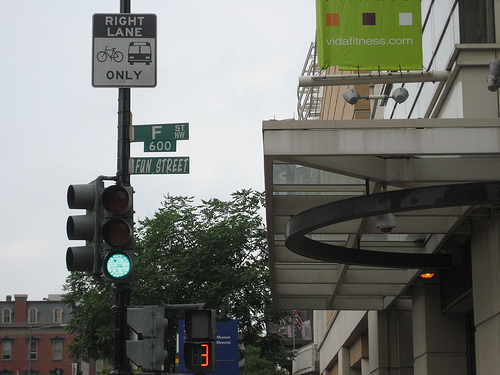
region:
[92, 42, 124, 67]
A black bike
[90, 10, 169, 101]
A black and white lane sign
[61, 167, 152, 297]
A street light that is green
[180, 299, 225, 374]
Crosswalk light says 3 in orange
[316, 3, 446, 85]
A green business banner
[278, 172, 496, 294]
A black half circle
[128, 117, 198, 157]
Green and white street sign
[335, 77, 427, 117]
Small grey spot lights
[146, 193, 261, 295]
A green tree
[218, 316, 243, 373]
Blue city banner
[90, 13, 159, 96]
A black and white right lane sign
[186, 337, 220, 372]
An orange number three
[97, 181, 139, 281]
A green light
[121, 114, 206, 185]
Two green street signs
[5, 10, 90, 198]
Blue grey sky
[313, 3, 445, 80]
A green fitness business sign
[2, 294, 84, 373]
A red and grey brick building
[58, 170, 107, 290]
A black stop light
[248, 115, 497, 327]
A building awning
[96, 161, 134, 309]
green traffic signal light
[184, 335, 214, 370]
number three on crosswalk signal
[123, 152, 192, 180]
green and white street sign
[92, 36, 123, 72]
bicycle on street sign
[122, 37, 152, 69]
picture of a bus on a street sign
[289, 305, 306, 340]
red and white striped flag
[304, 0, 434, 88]
green banner hanging above building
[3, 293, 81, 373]
red brick apartment building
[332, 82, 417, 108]
spotlights on the side of a building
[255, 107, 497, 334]
covered entry of building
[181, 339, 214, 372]
Street crossing signal showing 3 seconds left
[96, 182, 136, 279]
Green traffic light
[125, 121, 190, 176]
Street name signs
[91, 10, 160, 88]
Sign indicating right lane is only for bikes and buses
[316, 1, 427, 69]
Green business sign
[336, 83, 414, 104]
Spotlights aimed at sign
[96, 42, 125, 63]
Bicycle symbol on sign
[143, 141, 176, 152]
Sign indicating it's the 600 block of the street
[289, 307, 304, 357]
American flag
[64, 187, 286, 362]
Tree with green leaves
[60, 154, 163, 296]
green light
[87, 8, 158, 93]
sign for buses and bicycles only in right lane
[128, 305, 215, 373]
sign for people walking across road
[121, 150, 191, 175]
sign that says Fun Street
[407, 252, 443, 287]
light under building canopy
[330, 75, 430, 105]
two lights for sign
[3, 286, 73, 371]
an house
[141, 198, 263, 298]
a tree behind green light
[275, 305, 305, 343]
American flag on building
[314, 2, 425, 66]
sign on building for vida fitness.com